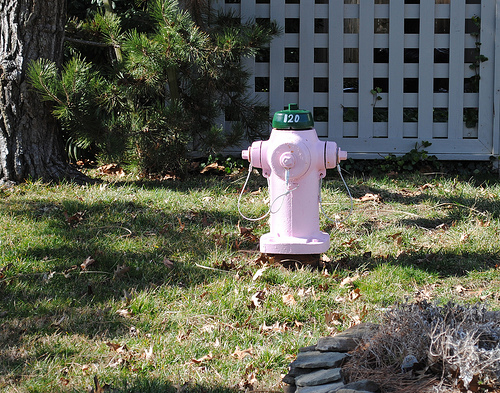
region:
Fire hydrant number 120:
[245, 98, 332, 143]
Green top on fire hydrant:
[262, 100, 322, 132]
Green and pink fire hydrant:
[235, 100, 355, 264]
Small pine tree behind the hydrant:
[49, 3, 256, 178]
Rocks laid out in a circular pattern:
[276, 302, 412, 391]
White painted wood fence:
[244, 3, 499, 148]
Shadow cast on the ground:
[1, 175, 248, 382]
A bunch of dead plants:
[356, 288, 496, 392]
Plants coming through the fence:
[461, 11, 488, 116]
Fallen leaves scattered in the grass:
[10, 178, 262, 382]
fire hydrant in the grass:
[235, 106, 360, 263]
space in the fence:
[459, 108, 474, 122]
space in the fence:
[402, 110, 427, 127]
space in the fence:
[370, 111, 392, 123]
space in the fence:
[365, 106, 392, 126]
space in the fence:
[340, 110, 366, 129]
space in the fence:
[341, 80, 363, 96]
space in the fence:
[372, 78, 391, 91]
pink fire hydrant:
[234, 103, 353, 268]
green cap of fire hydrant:
[273, 103, 313, 128]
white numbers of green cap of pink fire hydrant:
[260, 104, 316, 127]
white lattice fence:
[237, 3, 492, 159]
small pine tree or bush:
[39, 5, 276, 173]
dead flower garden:
[344, 307, 493, 392]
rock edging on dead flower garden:
[285, 324, 379, 390]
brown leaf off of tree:
[75, 247, 93, 280]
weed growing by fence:
[371, 134, 438, 174]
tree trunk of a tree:
[2, 5, 88, 190]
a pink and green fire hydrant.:
[220, 91, 348, 266]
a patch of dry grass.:
[277, 290, 498, 390]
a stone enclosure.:
[293, 287, 403, 392]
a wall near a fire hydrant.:
[240, 2, 497, 161]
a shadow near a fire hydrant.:
[328, 240, 498, 278]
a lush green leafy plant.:
[10, 0, 270, 181]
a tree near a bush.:
[0, 0, 35, 185]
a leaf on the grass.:
[229, 327, 260, 369]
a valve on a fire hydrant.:
[263, 137, 306, 183]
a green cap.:
[264, 97, 318, 137]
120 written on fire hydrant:
[278, 111, 303, 126]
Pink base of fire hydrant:
[242, 130, 347, 267]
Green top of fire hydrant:
[265, 104, 320, 131]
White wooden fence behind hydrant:
[169, 1, 498, 165]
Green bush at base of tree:
[27, 6, 274, 209]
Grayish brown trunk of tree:
[0, 1, 114, 200]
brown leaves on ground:
[75, 204, 483, 365]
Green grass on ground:
[0, 170, 498, 388]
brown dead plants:
[348, 297, 497, 390]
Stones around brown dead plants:
[277, 309, 391, 391]